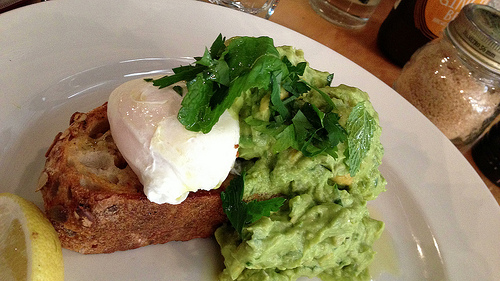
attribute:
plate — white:
[78, 10, 144, 35]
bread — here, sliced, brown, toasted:
[58, 134, 111, 230]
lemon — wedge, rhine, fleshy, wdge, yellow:
[7, 208, 55, 254]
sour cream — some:
[172, 152, 236, 175]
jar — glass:
[411, 35, 475, 135]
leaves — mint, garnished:
[219, 49, 284, 95]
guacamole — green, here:
[283, 191, 334, 242]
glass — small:
[316, 0, 376, 30]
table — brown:
[356, 48, 367, 60]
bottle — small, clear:
[377, 10, 394, 63]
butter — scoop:
[152, 178, 184, 202]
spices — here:
[449, 107, 480, 129]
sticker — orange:
[422, 9, 439, 28]